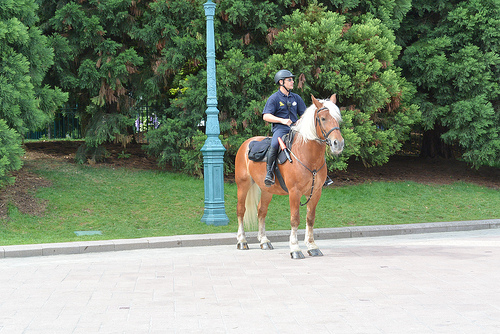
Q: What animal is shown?
A: A horse.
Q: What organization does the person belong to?
A: The police department.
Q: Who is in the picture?
A: A policeman.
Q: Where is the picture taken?
A: A street.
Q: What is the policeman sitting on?
A: A horse.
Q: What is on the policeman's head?
A: Helmet.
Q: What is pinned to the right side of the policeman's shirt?
A: Badge.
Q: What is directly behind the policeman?
A: A light pole.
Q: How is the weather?
A: Sunny.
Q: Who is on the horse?
A: Patrol officer.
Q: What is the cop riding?
A: A horse.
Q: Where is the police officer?
A: In the park.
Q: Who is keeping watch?
A: Police officer.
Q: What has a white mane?
A: The horse.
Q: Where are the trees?
A: In a park.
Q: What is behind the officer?
A: Trees.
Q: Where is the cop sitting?
A: On a horse.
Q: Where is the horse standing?
A: In the street.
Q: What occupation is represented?
A: Police officer.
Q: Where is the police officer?
A: Sitting on a horse.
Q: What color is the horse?
A: Light brown.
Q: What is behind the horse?
A: A pole.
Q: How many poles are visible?
A: One.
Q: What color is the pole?
A: Blue.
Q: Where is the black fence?
A: To the left of the pole, behind the trees.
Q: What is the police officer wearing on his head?
A: A helmet.